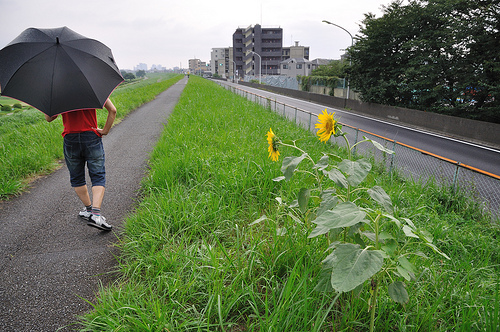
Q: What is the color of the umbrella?
A: Black.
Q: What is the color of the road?
A: Grey.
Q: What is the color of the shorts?
A: Blue.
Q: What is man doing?
A: Walking with umbrella.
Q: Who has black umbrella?
A: Man walking.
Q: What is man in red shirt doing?
A: Walking with umbrella.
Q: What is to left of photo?
A: Man walking with umbrella.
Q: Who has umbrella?
A: Man walking.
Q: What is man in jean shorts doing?
A: Walking with umbrella.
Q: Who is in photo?
A: Man walking with umbrella.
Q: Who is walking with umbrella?
A: A person.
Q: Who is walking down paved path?
A: The man.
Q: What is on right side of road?
A: Leafy tree top.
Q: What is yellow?
A: Plant with flowers.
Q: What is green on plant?
A: Leaves.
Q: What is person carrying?
A: Black umbrella.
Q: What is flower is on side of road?
A: Sunflower.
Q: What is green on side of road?
A: Grass.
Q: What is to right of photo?
A: Green trees.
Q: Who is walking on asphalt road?
A: A man walking.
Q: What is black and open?
A: Umbrella.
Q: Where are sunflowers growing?
A: Side of asphalt road.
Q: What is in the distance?
A: Buildings.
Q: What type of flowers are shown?
A: Sunflowers.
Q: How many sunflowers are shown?
A: 2.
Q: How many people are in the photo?
A: One.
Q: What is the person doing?
A: Walking.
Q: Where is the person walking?
A: On a path beside a road.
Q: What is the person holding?
A: An umbrella.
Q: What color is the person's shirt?
A: Red.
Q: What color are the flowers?
A: Yellow.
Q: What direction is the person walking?
A: Away from the camera.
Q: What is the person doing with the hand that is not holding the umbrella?
A: Resting it on their hip.